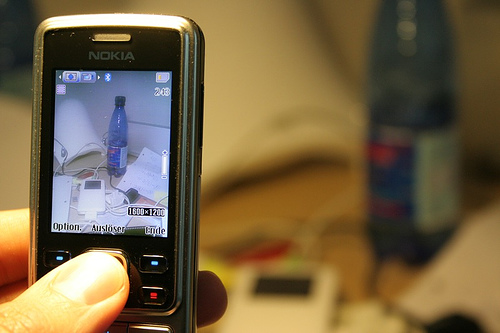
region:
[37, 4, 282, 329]
Phone in someone's hand.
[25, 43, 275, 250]
Screen of the phone.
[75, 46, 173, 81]
Brand of the phone.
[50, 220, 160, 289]
Buttons on the phone.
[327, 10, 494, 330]
Blurry bottle of water.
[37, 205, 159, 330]
person's finger on the phone.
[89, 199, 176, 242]
Options on the phone.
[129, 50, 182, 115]
Battery life on the phone.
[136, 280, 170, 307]
Red button on the phone.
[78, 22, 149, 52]
Speaker on the phone.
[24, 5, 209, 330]
a smart phone in a hand.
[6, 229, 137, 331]
a thumb on a phone.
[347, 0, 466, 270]
a bottle on a table.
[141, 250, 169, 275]
a green button.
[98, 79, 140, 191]
a bottle on an lcd screen.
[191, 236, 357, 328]
a book on a bed.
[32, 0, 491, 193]
a pillow on a bed.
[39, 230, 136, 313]
a thumb nail.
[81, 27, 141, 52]
a speaker on a phone.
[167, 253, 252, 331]
A finger behind a phone.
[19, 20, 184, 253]
Nokia cell phone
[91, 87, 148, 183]
Bottle on top of counter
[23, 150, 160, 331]
Person holding cellphone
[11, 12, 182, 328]
Person taking a photo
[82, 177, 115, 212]
Ipad on a counter top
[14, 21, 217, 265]
Black and silver cell phone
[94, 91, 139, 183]
Blue water bottle on counter top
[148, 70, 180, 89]
Cellphone with one energy bar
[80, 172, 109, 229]
Device charging up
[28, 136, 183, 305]
Person sending a photo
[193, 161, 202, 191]
edge of a phone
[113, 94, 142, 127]
part of a screen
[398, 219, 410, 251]
part of a bottle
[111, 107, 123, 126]
part of a camera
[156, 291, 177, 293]
part of a button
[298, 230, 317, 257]
part of a table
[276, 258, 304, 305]
part of a gadget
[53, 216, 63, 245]
part of a phone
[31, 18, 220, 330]
a old model phone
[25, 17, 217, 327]
a mobile no key pad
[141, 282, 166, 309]
end button of the mobile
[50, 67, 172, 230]
small display of the mobile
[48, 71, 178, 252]
white screen of the mobile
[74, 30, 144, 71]
name of the company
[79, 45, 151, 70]
text written on mobile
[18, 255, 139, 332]
a finger of the person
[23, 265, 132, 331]
a finger pressing buttons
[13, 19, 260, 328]
a hand holding mobile